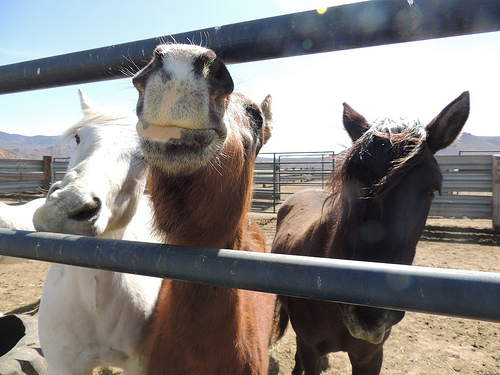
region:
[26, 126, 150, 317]
the horse is white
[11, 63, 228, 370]
the horse is white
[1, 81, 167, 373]
white horse in stable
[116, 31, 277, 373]
a sandy brown horse at stable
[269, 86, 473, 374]
dark chocolate horse at stable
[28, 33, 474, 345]
three heads to horses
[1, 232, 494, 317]
the gate has spots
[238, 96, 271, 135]
the eye of a horse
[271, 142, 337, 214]
entrance of stable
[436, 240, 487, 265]
plenty dirt on ground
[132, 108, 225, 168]
mouth of a horse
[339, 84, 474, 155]
ears of the horse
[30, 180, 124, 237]
NOSE AND MOUTH OF WHITE HORSE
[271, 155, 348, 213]
METAL GATE IN BACKGROUND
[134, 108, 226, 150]
LIPS OF BROWN HORSE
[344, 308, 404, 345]
BLACK HORSE MOUTH IS CLOSED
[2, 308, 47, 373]
TRACTOR TIRE ON GROUND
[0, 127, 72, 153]
MOUNTAINS IN BACKGROUND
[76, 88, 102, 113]
WHITE HORSE'S EAR IS UP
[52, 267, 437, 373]
FRONT CHESTS OF THREE HORSES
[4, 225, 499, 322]
METAL FENCE RAILING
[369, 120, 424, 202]
MANE HANGING BETWEEN EYES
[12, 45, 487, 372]
Three horses in a pen.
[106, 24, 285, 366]
Horse in the middle is brown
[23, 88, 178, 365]
Horse on the left is white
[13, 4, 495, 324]
Two bars of the fence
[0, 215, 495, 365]
The ground is dirt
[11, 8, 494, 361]
Photo taken during the day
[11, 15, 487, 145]
The sky is bright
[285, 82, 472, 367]
Horse on the right is black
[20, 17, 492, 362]
Nobody in the photo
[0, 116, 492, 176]
Mountains off in the background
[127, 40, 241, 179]
spotted nose on horse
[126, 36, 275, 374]
orange horse poking nose through fence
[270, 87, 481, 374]
dark brown horse on right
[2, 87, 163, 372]
white horse on left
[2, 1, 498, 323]
large black metal fence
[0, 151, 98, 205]
sheet metal fencing behind white horse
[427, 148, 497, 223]
sheet metal fencing behind brown horse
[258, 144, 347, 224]
fence gates behind horses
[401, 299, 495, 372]
hoof prints in soil behind horses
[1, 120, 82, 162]
mountain range behind white horse's head